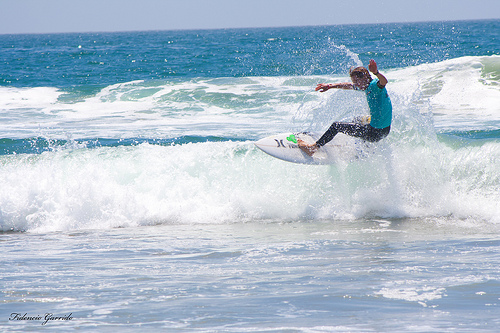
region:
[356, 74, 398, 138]
light blue shortsleeved rashguard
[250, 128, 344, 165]
The white surfboard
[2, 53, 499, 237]
The waves in the ocean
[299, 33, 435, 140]
The spray kicked up by the board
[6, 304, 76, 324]
The name of the photographer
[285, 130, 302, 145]
The green sticker on the board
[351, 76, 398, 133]
The blue shirt of the boarder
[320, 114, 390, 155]
The boarder's black pants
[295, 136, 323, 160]
The exposed foot of the boarder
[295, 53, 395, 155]
The man riding the surf board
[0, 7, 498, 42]
The horizon line in the ocean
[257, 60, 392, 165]
a man surfing on a white wave on the beach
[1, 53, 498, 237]
two white waves on the water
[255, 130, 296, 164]
the front tip of a white surfboard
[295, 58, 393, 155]
a man wearing black pants to a wetsuit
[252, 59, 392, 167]
a surfer leaning backward on a white surfboard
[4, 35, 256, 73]
blue water on the beach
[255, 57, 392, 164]
a man balancing on a water wave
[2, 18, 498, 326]
a man in a blue t-shirt surfing on the beach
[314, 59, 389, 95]
the arms of the surfer raised in the air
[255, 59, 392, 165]
a surfer about to fall off the surfboard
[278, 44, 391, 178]
SURFER CATCHING WAVE IN OCEAN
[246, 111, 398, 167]
POINTED WHITE SURF BOARD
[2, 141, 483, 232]
CRASHING WHITE WAVE UNDER SURFER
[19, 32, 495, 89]
CALM BLUE OCEAN BEHIND WAVES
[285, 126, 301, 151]
THREE GREEN CIRCLES ON BOARD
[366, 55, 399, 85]
SURFERS RAISED LEFT ARM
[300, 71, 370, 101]
SURFERS RIGHT ARM STICKING OUT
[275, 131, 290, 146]
SURFBOARD COMPANY LOGO ON BOARD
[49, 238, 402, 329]
WHITE FOAMY WATER BEFORE WAVE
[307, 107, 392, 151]
DARK TIGHT WET PANTS ON SURFER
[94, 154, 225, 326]
big splash of water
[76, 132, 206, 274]
big splash of water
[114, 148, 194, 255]
big splash of water